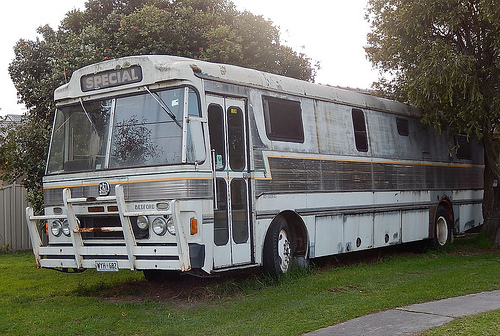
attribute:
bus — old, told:
[22, 49, 471, 278]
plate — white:
[91, 258, 122, 280]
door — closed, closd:
[206, 95, 271, 276]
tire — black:
[257, 218, 299, 291]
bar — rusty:
[73, 221, 125, 239]